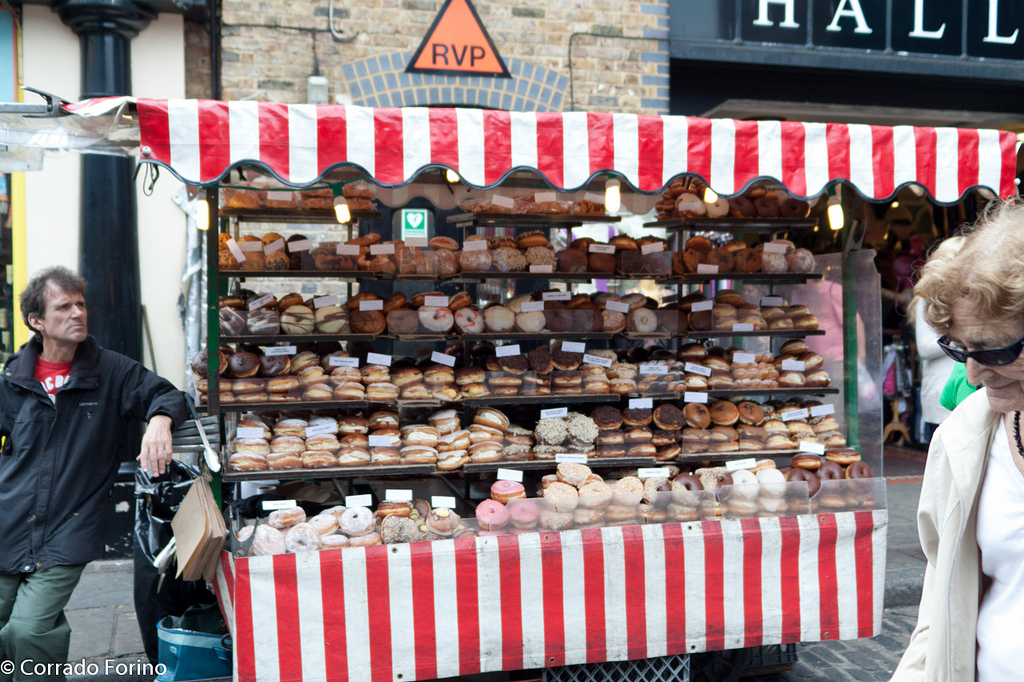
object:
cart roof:
[57, 95, 1016, 206]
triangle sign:
[403, 0, 513, 78]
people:
[892, 199, 1024, 682]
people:
[0, 267, 198, 682]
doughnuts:
[611, 476, 644, 507]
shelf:
[217, 395, 620, 413]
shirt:
[975, 411, 1024, 682]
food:
[476, 499, 512, 530]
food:
[580, 481, 615, 510]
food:
[570, 407, 594, 442]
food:
[654, 404, 689, 431]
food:
[710, 400, 740, 426]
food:
[625, 307, 657, 332]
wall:
[232, 31, 303, 95]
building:
[222, 1, 1022, 128]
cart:
[211, 508, 888, 682]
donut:
[492, 479, 528, 503]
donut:
[826, 447, 862, 465]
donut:
[556, 461, 592, 487]